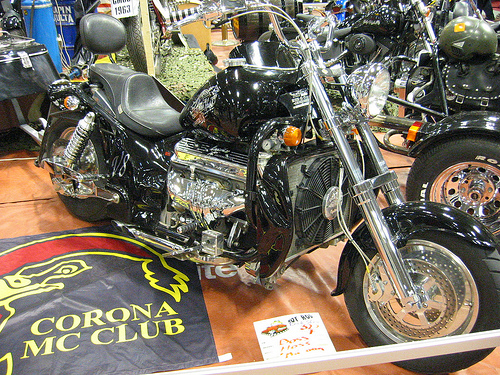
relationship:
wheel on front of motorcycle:
[344, 230, 500, 374] [34, 2, 499, 374]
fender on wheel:
[330, 199, 497, 299] [344, 230, 500, 374]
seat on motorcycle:
[79, 10, 187, 140] [34, 2, 499, 374]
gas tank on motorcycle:
[177, 41, 308, 146] [34, 2, 499, 374]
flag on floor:
[0, 221, 220, 372] [2, 26, 498, 374]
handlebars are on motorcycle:
[156, 0, 343, 53] [34, 2, 499, 374]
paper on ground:
[251, 310, 338, 363] [2, 26, 498, 374]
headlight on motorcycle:
[345, 62, 391, 121] [34, 2, 499, 374]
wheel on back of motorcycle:
[47, 120, 110, 224] [34, 2, 499, 374]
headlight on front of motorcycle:
[345, 62, 391, 121] [34, 2, 499, 374]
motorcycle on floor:
[34, 2, 499, 374] [2, 26, 498, 374]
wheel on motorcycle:
[344, 230, 500, 374] [34, 2, 499, 374]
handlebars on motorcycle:
[156, 0, 343, 53] [34, 2, 499, 374]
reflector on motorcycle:
[282, 123, 301, 148] [34, 2, 499, 374]